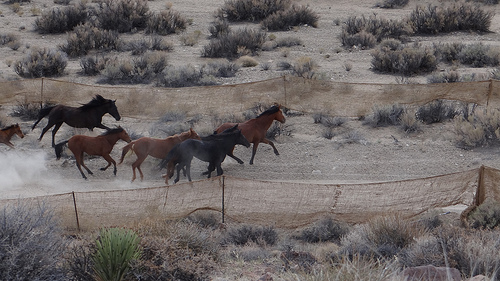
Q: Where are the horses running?
A: Desert.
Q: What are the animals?
A: Horses.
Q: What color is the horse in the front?
A: Brown.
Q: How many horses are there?
A: Six.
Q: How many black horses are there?
A: Two.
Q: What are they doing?
A: Running.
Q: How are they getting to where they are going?
A: Running.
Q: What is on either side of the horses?
A: Fence.